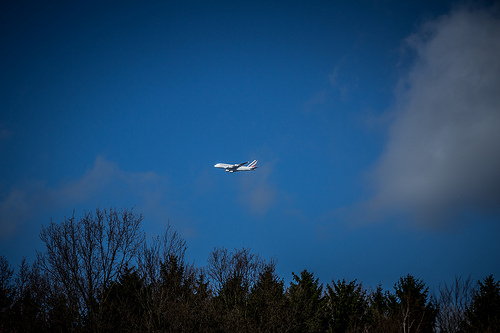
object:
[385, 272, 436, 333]
trees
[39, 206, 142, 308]
sticks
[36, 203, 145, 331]
tree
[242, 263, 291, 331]
tree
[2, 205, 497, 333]
forest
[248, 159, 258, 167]
tail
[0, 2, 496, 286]
sky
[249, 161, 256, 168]
logo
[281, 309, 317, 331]
leaves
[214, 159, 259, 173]
airplane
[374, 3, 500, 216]
cloud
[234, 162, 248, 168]
wing